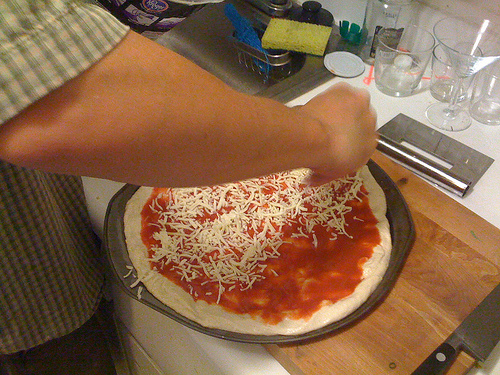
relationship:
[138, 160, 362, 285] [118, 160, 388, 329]
cheese on top of pizza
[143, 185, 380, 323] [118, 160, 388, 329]
pizza sauce on top of pizza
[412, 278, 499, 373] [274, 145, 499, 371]
knife on top of chopping block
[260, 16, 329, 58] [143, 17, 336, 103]
sponge on top of sink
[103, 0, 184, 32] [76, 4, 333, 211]
stopper for sink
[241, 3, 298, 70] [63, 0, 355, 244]
sponge holder in sink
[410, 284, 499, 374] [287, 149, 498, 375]
knife on top of chopping block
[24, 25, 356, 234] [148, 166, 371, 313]
man making pizza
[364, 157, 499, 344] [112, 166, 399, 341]
board under pizza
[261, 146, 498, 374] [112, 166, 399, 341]
board under pizza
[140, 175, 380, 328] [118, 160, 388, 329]
pizza sauce on pizza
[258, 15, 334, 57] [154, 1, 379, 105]
sponge on sink